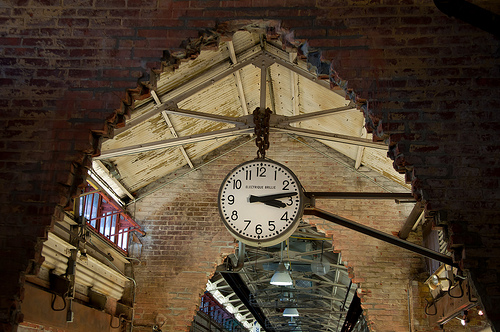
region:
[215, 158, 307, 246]
Round clock hanging from ceiling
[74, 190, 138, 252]
Red railing in building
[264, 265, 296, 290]
Hanging ceiling light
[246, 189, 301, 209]
Metallic clock hands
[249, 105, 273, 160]
Metal chain hanging from support arch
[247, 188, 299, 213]
Time displayed on clock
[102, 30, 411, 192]
Old wooden ceiling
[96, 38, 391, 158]
Metal ceiling support beams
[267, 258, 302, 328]
Row of lamps hanging from ceiling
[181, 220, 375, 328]
Entrance cut into brick wall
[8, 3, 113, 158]
The red brick building containing the clock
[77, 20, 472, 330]
The entrance to the building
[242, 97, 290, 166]
A heavy metal chain hanging up the clock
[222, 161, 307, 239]
A large circular clock hanging from the ceiling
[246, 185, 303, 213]
Two black hands on the face of the clock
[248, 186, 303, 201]
The long minute hand of the clock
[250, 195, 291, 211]
The short hour hand of the clock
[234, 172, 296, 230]
The clock says the time is 3:14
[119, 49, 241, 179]
The slanted roof is made of brown wood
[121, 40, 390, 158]
Metal beams holding the slanted roof up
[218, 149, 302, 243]
this is a clock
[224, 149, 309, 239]
the clock is hanged above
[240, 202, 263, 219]
the clock is white in color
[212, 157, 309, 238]
the clock is big in size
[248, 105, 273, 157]
this is a chain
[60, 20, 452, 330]
the door is open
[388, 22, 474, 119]
the wall is made of bricks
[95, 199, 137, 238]
this is the window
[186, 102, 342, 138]
the metals are above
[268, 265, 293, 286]
the light is on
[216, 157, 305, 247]
The clock face is white.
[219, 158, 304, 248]
The clock is round.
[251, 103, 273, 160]
A chain holds the clock from the ceiling.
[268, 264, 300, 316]
Lights hang from the trusses.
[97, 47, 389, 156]
Trusses are supporting the ceiling.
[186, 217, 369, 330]
The entrance way is arched.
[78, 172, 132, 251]
The windows are letting in sunlight.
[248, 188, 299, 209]
The clock hands are black.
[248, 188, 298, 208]
The clock hands indicate it is 3:13.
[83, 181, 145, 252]
The metalwork appears orange.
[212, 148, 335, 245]
White clock in center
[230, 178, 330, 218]
Black arms on white clock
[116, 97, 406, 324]
Brick wall with hole in it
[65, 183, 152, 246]
Red rail on left of building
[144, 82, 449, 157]
White metal rails on roof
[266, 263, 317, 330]
LAMPS THROUGH THE OPENING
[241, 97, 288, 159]
Rusty chain holding clock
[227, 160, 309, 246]
Black number on clock face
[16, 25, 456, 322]
Opening in bricks in the foreground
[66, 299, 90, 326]
Small gray electrical box